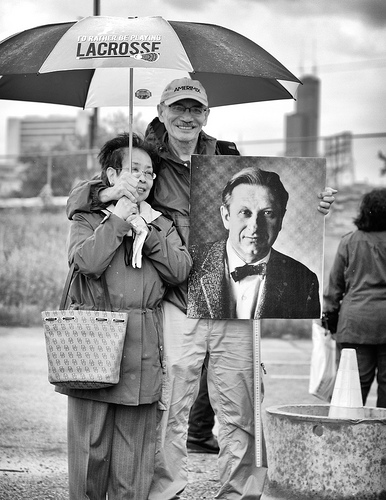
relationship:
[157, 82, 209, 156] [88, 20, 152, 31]
man holding umbrella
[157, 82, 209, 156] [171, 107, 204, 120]
man wearing sunglasess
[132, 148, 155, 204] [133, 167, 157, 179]
woman wearing glasses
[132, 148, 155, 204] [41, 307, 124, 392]
woman has purse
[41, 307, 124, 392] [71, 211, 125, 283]
purse on arm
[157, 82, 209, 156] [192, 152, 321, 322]
man holding portrait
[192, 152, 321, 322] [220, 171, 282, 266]
portrait of man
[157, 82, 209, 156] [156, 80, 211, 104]
man wearing cap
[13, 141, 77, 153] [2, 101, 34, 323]
tree on side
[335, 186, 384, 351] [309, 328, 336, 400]
person carrying bag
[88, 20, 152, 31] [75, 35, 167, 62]
umbrella has logo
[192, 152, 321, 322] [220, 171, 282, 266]
photo of man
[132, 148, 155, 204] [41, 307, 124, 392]
woman carrying handbag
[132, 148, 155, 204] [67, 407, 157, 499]
woman wearing pants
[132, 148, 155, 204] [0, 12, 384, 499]
woman in photo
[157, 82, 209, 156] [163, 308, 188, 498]
man wearing pants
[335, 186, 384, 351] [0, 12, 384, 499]
woman in photo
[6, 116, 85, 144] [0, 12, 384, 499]
building in photo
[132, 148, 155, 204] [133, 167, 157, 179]
woman wearing spectacles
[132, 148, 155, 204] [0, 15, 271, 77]
woman holding umbrella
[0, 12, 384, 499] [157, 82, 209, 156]
post of person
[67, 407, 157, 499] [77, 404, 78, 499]
pants have pinstripe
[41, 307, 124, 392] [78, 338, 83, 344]
bag of bourke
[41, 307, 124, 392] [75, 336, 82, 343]
bag of dooney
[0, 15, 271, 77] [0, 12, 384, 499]
umbrella in photo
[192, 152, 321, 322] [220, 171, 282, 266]
poster of man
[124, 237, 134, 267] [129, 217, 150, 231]
gloves in hand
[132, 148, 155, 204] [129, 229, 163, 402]
woman in jacket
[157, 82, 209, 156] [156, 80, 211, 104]
man wearing hat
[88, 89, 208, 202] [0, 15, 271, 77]
couple underneath of umbrella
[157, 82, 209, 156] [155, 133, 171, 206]
man wearing jacket